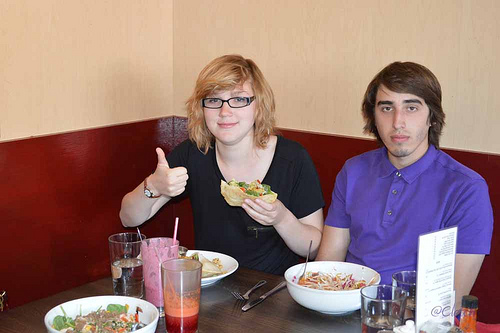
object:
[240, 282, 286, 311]
knife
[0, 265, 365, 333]
table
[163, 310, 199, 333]
juice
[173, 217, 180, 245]
straw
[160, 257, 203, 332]
glass